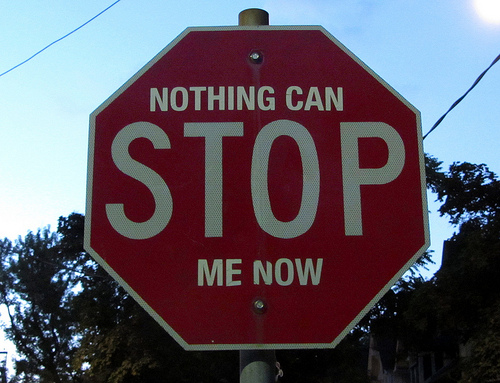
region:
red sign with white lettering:
[74, 8, 427, 360]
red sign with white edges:
[76, 13, 441, 362]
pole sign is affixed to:
[233, 6, 282, 378]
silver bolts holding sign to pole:
[246, 45, 269, 339]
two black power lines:
[2, 10, 489, 203]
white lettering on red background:
[103, 123, 405, 243]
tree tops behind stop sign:
[6, 170, 483, 381]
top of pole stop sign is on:
[238, 3, 272, 33]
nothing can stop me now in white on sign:
[100, 78, 410, 303]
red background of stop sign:
[100, 20, 417, 332]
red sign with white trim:
[76, 12, 425, 355]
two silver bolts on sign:
[250, 49, 268, 314]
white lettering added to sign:
[147, 71, 342, 296]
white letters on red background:
[105, 117, 397, 242]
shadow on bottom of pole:
[213, 346, 285, 368]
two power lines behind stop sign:
[1, 5, 491, 256]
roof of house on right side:
[357, 317, 497, 376]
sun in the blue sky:
[465, 2, 499, 25]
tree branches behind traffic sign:
[9, 156, 498, 379]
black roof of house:
[371, 308, 428, 356]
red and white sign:
[112, 20, 420, 345]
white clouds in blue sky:
[1, 9, 81, 73]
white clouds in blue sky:
[8, 89, 82, 143]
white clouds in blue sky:
[5, 139, 85, 197]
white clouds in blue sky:
[68, 26, 120, 58]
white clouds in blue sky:
[341, 10, 424, 57]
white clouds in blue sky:
[410, 35, 465, 97]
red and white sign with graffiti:
[91, 20, 423, 335]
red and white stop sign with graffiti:
[97, 21, 397, 347]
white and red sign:
[112, 110, 403, 246]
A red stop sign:
[80, 21, 433, 341]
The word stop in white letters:
[104, 118, 413, 240]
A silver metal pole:
[242, 350, 285, 381]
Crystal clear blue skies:
[56, 55, 112, 90]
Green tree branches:
[20, 245, 81, 365]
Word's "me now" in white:
[193, 255, 329, 293]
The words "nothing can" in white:
[141, 80, 357, 115]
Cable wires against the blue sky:
[455, 70, 498, 91]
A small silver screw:
[250, 292, 270, 310]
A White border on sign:
[160, 335, 352, 354]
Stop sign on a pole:
[109, 30, 426, 337]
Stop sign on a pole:
[61, 116, 343, 346]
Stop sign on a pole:
[61, 200, 436, 359]